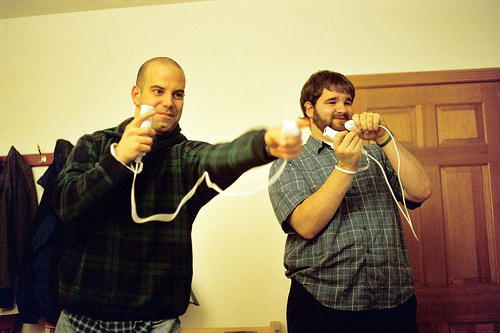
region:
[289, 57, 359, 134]
head of a person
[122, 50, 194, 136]
head of a person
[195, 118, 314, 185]
arm of a person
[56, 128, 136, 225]
arm of a person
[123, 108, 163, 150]
hand of a person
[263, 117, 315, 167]
hand of a person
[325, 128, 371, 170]
hand of a person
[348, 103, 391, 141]
hand of a person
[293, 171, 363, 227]
arm of a person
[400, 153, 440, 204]
elbow of a person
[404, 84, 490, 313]
wooden door on right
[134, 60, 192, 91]
short hair on head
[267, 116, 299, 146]
wii controller in hand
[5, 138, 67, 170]
coat rack on wall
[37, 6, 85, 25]
ceiling of the wall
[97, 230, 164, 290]
dark shirt on man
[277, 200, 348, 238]
the elbow of man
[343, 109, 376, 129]
the hand of man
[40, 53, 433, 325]
Two men playing nintendo wii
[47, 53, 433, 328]
Two men playing nintendo wii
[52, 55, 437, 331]
Two men playing nintendo wii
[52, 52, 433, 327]
Two men playing nintendo wii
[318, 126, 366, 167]
wii controller in the hand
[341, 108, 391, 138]
hand holding the wii nunchuck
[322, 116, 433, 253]
white cord connecting the controller to the nunchuck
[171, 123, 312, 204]
arm is extended in front of the body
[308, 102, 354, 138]
brown hair along the jawline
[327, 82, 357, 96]
hair laying on the forehead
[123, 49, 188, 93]
only stubble on the head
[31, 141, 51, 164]
gold hook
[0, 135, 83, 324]
jackets hanging on the wall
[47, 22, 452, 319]
two men standing together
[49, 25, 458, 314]
two men holding remote controls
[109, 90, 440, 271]
remote controls are white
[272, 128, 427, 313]
man wearing plaid shirt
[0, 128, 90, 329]
two jackets hanging on rack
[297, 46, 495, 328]
brown door behind man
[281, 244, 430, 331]
man wearing black bottoms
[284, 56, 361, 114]
man with brown hair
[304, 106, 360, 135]
man with brown beard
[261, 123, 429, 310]
big plaid shirt guy is wearing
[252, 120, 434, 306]
big plaid shirt guy is wearing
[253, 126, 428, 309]
big plaid shirt guy is wearing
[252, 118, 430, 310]
big plaid shirt guy is wearing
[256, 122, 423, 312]
big plaid shirt guy is wearing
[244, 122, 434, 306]
big plaid shirt guy is wearing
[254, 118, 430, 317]
big plaid shirt guy is wearing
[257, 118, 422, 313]
big plaid shirt guy is wearing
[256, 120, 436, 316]
big plaid shirt guy is wearing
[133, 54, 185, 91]
shaved head of a man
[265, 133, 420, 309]
short sleeved plaid shirt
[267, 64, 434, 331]
man wearing a short sleeved shirt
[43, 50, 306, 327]
man wearing a long sleeved shirt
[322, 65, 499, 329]
door made of wood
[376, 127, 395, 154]
band around a man's arm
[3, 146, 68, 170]
coat rack on the wall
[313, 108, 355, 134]
facial hair on a man